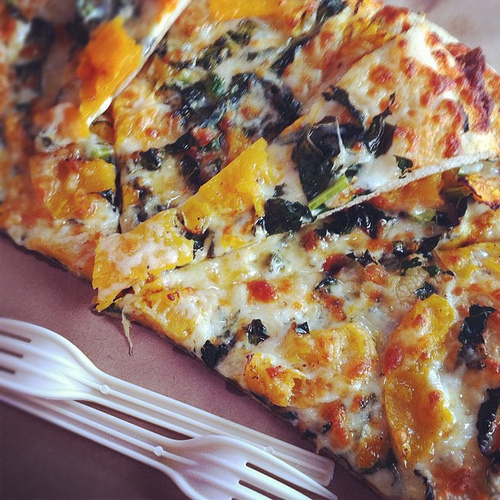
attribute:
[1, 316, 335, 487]
forks — plastic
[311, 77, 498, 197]
pizza —  browned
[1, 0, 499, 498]
lunch — nutritious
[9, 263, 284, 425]
table —  pinkish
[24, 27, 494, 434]
flatbread — is melted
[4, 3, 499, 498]
table — is gray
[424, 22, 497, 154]
pizza crust — is thin, is rolled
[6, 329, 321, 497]
forks — are plastic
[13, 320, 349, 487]
fork — is plastic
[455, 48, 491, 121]
pizza crust — is burnt 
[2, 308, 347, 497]
forks — are white, are plastic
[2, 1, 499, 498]
pizza — is flat, delicious, is cooked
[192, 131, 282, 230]
topping — is cooked